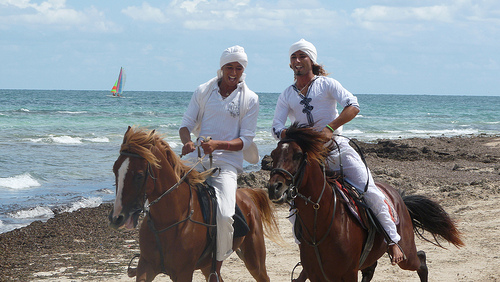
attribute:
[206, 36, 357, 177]
riders — talking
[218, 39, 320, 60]
turbans — white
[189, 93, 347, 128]
outfits — white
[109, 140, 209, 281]
horse — brown, galloping, white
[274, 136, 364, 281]
horse — galloping, brown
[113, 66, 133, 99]
sailboat — colorful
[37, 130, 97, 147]
waves — small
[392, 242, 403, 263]
foot — bare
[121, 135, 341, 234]
horses — running, brown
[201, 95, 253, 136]
clothes — white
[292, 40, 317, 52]
turban — white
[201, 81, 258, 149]
shirt — white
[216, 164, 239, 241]
pants — white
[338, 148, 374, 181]
pants — white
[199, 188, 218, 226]
saddle — black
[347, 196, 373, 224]
saddle — black